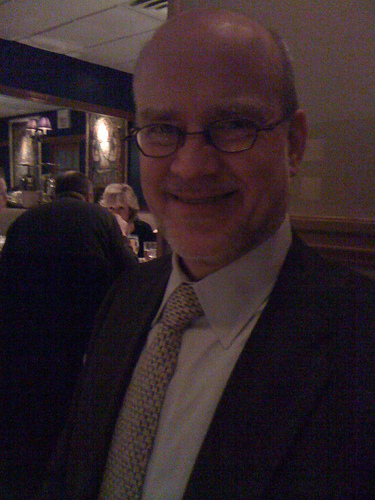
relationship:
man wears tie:
[36, 6, 373, 497] [92, 271, 204, 498]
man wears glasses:
[36, 6, 373, 497] [120, 114, 296, 159]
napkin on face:
[112, 212, 129, 237] [137, 7, 303, 263]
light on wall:
[39, 115, 54, 134] [4, 114, 136, 201]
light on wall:
[22, 117, 40, 131] [4, 114, 136, 201]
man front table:
[5, 167, 145, 273] [124, 241, 158, 267]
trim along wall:
[282, 218, 373, 248] [263, 7, 372, 235]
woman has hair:
[94, 181, 154, 256] [95, 181, 140, 218]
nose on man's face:
[165, 144, 225, 189] [125, 7, 305, 260]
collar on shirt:
[149, 213, 291, 349] [40, 213, 374, 498]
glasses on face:
[120, 114, 296, 159] [135, 106, 268, 234]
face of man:
[135, 106, 268, 234] [36, 6, 373, 497]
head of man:
[130, 5, 306, 258] [36, 6, 373, 497]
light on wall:
[39, 115, 54, 134] [14, 115, 85, 133]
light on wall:
[22, 117, 40, 131] [14, 115, 85, 133]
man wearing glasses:
[36, 6, 373, 497] [126, 106, 291, 176]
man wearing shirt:
[36, 6, 373, 497] [101, 263, 262, 466]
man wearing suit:
[36, 6, 373, 497] [50, 213, 373, 498]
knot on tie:
[152, 288, 209, 329] [100, 287, 204, 498]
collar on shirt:
[149, 213, 291, 349] [141, 209, 291, 499]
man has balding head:
[36, 6, 373, 497] [127, 5, 301, 125]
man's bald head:
[123, 27, 313, 262] [135, 9, 298, 266]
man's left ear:
[123, 27, 313, 262] [279, 100, 320, 171]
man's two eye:
[123, 27, 313, 262] [146, 119, 182, 137]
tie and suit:
[87, 283, 202, 494] [78, 272, 354, 496]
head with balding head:
[130, 5, 306, 258] [127, 5, 301, 125]